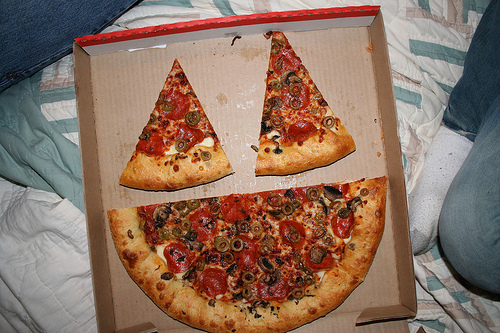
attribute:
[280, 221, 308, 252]
topping — red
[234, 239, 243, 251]
olive slice — green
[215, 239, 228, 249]
olive slice — green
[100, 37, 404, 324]
pizza — sliced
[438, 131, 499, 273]
jean — denim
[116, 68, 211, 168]
pizza — sliced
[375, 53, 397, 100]
box — red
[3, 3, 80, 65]
jeans — blue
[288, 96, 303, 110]
olives — round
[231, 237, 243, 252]
olives — round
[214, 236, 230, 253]
olives — round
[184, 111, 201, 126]
olives — round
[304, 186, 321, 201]
olives — round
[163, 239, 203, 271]
pepperoni — red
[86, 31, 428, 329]
box — brown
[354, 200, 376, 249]
crust — thick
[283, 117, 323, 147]
pepperoni — red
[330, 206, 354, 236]
pepperoni — red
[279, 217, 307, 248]
pepperoni — red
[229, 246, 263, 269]
pepperoni — red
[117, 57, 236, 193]
pizza slice — small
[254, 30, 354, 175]
pizza slice — small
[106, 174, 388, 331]
pizza slice — big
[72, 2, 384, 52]
edge — red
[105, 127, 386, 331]
crust — golden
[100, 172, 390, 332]
pizza — halved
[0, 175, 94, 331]
blanket — white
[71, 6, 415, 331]
box — cardboard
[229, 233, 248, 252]
topping — circular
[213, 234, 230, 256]
topping — circular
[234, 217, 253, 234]
topping — circular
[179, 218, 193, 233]
topping — circular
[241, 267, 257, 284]
topping — circular